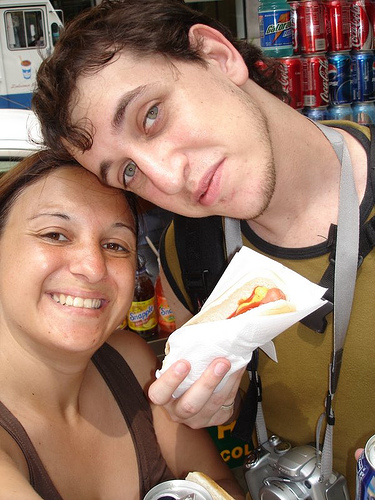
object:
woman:
[0, 145, 241, 500]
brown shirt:
[0, 341, 170, 500]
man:
[30, 0, 375, 500]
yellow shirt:
[157, 116, 375, 500]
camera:
[240, 432, 351, 500]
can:
[293, 0, 330, 60]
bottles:
[253, 0, 295, 65]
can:
[346, 51, 374, 104]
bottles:
[125, 249, 177, 344]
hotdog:
[151, 257, 309, 402]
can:
[297, 49, 334, 112]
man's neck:
[245, 96, 364, 257]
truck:
[0, 0, 68, 155]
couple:
[0, 0, 374, 499]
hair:
[0, 141, 81, 232]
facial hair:
[230, 91, 279, 226]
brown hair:
[25, 0, 291, 159]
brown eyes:
[34, 223, 132, 258]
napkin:
[233, 253, 264, 283]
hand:
[144, 352, 250, 434]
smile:
[41, 285, 114, 316]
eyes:
[119, 96, 168, 191]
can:
[345, 0, 374, 53]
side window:
[0, 1, 51, 56]